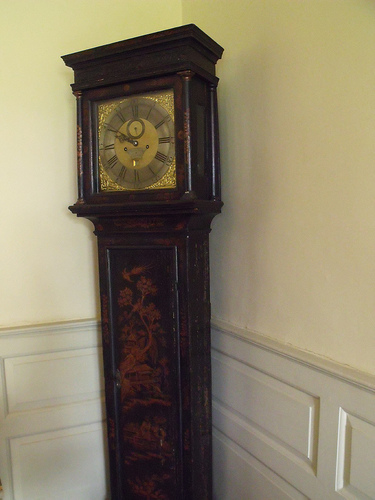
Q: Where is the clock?
A: A corner.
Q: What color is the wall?
A: White.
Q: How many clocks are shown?
A: One.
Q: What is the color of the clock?
A: Brown.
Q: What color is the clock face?
A: Gold.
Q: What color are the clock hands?
A: Black.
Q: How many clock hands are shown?
A: Two.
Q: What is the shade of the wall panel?
A: White.